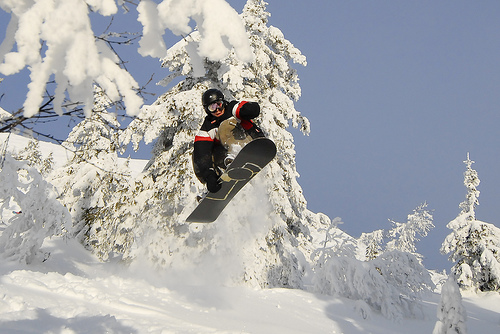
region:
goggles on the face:
[204, 98, 227, 113]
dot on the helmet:
[209, 92, 214, 101]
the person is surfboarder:
[200, 97, 272, 178]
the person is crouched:
[200, 92, 247, 170]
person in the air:
[203, 82, 266, 217]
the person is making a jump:
[185, 85, 276, 227]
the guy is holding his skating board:
[182, 89, 276, 223]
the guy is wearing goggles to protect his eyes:
[184, 86, 275, 226]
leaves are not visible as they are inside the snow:
[4, 3, 141, 117]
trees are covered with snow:
[5, 3, 497, 304]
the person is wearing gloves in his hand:
[182, 89, 276, 226]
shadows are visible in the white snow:
[5, 165, 496, 332]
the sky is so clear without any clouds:
[301, 9, 498, 204]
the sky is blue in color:
[307, 11, 492, 199]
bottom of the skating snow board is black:
[182, 138, 276, 225]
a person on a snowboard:
[159, 78, 284, 232]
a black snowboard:
[165, 133, 282, 241]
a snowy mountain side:
[6, 124, 480, 326]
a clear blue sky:
[7, 6, 486, 255]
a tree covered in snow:
[155, 2, 315, 299]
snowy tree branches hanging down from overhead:
[0, 21, 266, 101]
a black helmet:
[200, 84, 226, 112]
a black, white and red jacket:
[177, 105, 290, 184]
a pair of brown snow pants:
[215, 115, 257, 165]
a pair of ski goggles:
[200, 98, 227, 113]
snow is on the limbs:
[142, 79, 212, 144]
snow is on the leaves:
[29, 15, 110, 103]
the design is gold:
[217, 167, 258, 212]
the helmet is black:
[202, 88, 218, 100]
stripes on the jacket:
[197, 127, 229, 137]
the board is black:
[197, 143, 270, 224]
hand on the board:
[204, 172, 229, 217]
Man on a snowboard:
[160, 78, 280, 237]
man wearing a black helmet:
[193, 88, 229, 102]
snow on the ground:
[130, 264, 277, 332]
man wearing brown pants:
[215, 115, 256, 144]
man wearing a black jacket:
[177, 103, 270, 158]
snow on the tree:
[448, 153, 498, 266]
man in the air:
[166, 78, 287, 232]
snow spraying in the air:
[128, 220, 275, 290]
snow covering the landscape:
[279, 198, 440, 306]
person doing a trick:
[159, 51, 296, 236]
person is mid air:
[161, 62, 287, 258]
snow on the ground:
[26, 197, 468, 329]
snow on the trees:
[11, 7, 491, 312]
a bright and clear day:
[11, 7, 497, 329]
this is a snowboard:
[177, 137, 287, 236]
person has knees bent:
[189, 114, 261, 199]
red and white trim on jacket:
[173, 101, 261, 144]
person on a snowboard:
[155, 61, 292, 241]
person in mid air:
[139, 57, 308, 256]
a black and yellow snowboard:
[168, 132, 282, 233]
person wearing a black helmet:
[191, 85, 232, 115]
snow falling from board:
[126, 176, 284, 311]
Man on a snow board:
[164, 77, 295, 228]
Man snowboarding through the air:
[163, 84, 284, 224]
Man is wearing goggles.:
[175, 86, 281, 228]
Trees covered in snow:
[135, 27, 498, 295]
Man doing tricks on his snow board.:
[170, 86, 293, 233]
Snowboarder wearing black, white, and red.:
[182, 84, 275, 228]